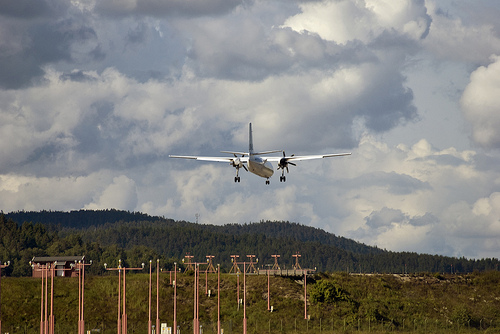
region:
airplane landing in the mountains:
[176, 107, 346, 219]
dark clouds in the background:
[45, 7, 230, 217]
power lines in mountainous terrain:
[24, 220, 309, 332]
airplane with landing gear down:
[165, 113, 352, 208]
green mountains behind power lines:
[48, 181, 269, 332]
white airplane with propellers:
[180, 107, 359, 217]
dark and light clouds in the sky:
[10, 3, 497, 143]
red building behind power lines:
[2, 233, 112, 308]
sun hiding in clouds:
[256, 2, 432, 128]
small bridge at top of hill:
[174, 249, 326, 276]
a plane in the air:
[155, 97, 340, 189]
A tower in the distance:
[166, 190, 215, 226]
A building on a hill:
[13, 242, 94, 284]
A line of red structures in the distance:
[176, 250, 318, 265]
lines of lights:
[23, 264, 323, 329]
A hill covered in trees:
[248, 212, 307, 242]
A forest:
[5, 193, 467, 268]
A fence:
[206, 310, 491, 332]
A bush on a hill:
[303, 274, 360, 304]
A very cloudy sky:
[3, 3, 468, 209]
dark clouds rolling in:
[3, 39, 70, 95]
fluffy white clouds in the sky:
[356, 55, 447, 170]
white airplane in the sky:
[161, 119, 358, 190]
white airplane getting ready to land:
[158, 115, 355, 195]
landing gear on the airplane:
[229, 172, 293, 188]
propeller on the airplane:
[277, 145, 298, 170]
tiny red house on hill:
[33, 247, 86, 282]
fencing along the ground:
[268, 313, 429, 328]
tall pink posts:
[21, 256, 66, 329]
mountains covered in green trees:
[102, 209, 179, 249]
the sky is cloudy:
[51, 35, 181, 95]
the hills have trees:
[26, 197, 290, 314]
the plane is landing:
[110, 80, 422, 239]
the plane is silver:
[141, 113, 399, 268]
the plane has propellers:
[148, 103, 418, 200]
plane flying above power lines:
[81, 105, 419, 320]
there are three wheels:
[130, 102, 419, 248]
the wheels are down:
[151, 101, 367, 213]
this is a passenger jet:
[138, 95, 375, 242]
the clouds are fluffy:
[31, 97, 152, 167]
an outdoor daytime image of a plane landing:
[1, 0, 498, 332]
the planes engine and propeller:
[277, 152, 294, 172]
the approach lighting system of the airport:
[29, 250, 329, 332]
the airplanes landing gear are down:
[279, 166, 286, 181]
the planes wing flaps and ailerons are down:
[168, 151, 248, 165]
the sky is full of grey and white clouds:
[1, 1, 499, 121]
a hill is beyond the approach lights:
[1, 206, 496, 269]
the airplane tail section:
[225, 122, 282, 155]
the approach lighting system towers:
[1, 252, 351, 332]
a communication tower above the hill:
[193, 211, 201, 226]